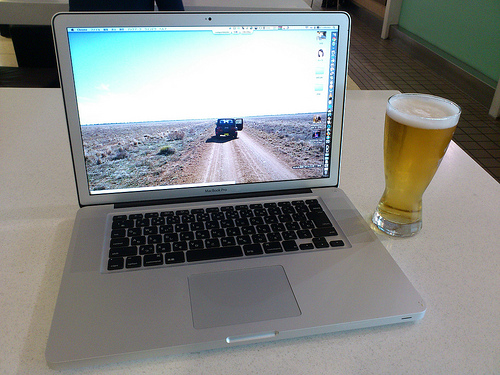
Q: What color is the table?
A: White.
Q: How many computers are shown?
A: 1.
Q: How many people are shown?
A: 0.